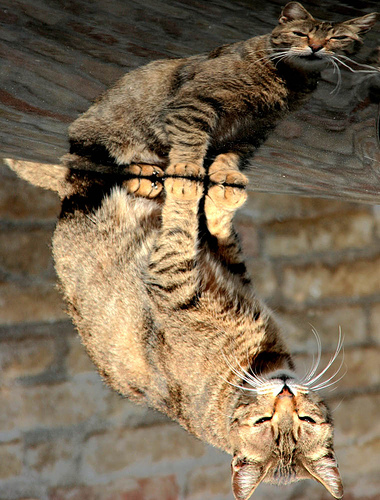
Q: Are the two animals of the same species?
A: Yes, all the animals are cats.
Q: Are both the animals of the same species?
A: Yes, all the animals are cats.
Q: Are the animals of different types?
A: No, all the animals are cats.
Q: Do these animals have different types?
A: No, all the animals are cats.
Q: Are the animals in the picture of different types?
A: No, all the animals are cats.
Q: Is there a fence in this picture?
A: No, there are no fences.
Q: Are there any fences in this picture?
A: No, there are no fences.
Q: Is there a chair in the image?
A: No, there are no chairs.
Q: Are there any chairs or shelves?
A: No, there are no chairs or shelves.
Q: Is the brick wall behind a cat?
A: Yes, the wall is behind a cat.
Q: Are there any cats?
A: Yes, there is a cat.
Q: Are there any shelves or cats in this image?
A: Yes, there is a cat.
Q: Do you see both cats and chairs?
A: No, there is a cat but no chairs.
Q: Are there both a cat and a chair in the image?
A: No, there is a cat but no chairs.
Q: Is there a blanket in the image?
A: No, there are no blankets.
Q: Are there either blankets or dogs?
A: No, there are no blankets or dogs.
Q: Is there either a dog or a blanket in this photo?
A: No, there are no blankets or dogs.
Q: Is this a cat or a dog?
A: This is a cat.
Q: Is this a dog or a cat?
A: This is a cat.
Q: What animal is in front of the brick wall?
A: The cat is in front of the wall.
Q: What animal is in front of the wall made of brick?
A: The animal is a cat.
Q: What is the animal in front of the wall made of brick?
A: The animal is a cat.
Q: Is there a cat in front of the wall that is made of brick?
A: Yes, there is a cat in front of the wall.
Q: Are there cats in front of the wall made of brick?
A: Yes, there is a cat in front of the wall.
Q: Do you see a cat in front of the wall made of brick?
A: Yes, there is a cat in front of the wall.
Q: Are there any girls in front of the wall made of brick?
A: No, there is a cat in front of the wall.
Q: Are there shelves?
A: No, there are no shelves.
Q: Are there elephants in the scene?
A: No, there are no elephants.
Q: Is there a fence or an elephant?
A: No, there are no elephants or fences.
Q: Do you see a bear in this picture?
A: No, there are no bears.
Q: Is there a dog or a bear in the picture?
A: No, there are no bears or dogs.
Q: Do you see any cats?
A: Yes, there is a cat.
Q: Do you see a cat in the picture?
A: Yes, there is a cat.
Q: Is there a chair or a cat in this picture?
A: Yes, there is a cat.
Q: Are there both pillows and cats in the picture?
A: No, there is a cat but no pillows.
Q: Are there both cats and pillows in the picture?
A: No, there is a cat but no pillows.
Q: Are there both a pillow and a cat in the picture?
A: No, there is a cat but no pillows.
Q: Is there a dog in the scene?
A: No, there are no dogs.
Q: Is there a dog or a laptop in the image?
A: No, there are no dogs or laptops.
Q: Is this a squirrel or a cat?
A: This is a cat.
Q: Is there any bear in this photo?
A: No, there are no bears.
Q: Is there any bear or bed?
A: No, there are no bears or beds.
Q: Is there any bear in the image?
A: No, there are no bears.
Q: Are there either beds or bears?
A: No, there are no bears or beds.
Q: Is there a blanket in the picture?
A: No, there are no blankets.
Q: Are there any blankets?
A: No, there are no blankets.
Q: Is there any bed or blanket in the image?
A: No, there are no blankets or beds.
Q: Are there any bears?
A: No, there are no bears.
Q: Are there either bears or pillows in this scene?
A: No, there are no bears or pillows.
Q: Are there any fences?
A: No, there are no fences.